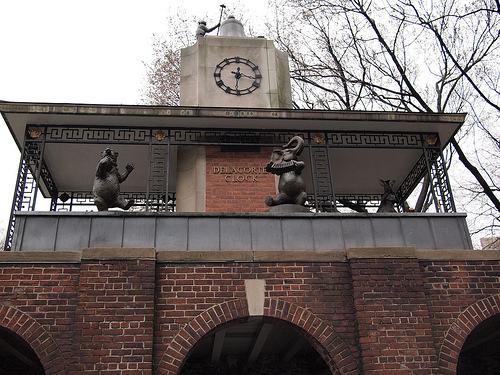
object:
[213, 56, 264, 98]
clock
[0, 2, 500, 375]
clock tower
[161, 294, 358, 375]
archway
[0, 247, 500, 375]
wall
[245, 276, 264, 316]
capstone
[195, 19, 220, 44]
statue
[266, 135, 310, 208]
statue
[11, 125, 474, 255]
2nd floor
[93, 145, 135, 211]
bear statue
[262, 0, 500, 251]
tree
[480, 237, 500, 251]
roof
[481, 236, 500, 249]
odd building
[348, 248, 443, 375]
column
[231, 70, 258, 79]
pointed hand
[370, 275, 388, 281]
brick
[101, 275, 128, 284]
dark spots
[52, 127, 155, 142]
design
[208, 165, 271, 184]
sign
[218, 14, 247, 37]
bell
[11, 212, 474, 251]
metal wall